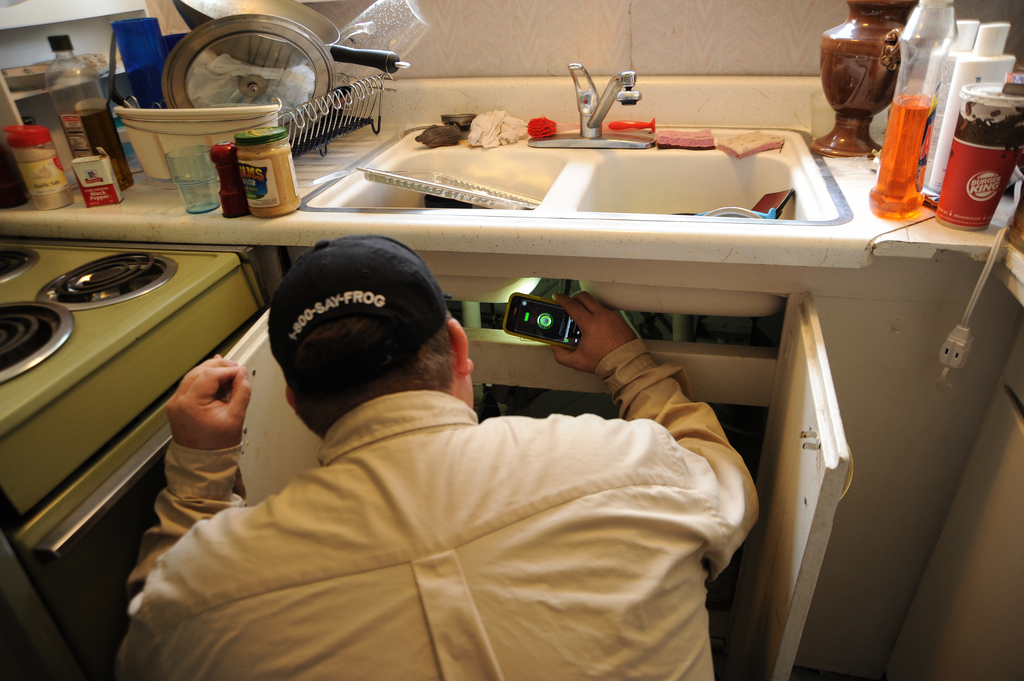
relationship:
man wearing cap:
[115, 237, 761, 678] [264, 234, 451, 404]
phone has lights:
[487, 277, 640, 389] [519, 297, 562, 333]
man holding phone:
[115, 237, 761, 678] [500, 292, 583, 352]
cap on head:
[265, 234, 452, 374] [265, 234, 481, 421]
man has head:
[115, 237, 761, 678] [265, 234, 481, 421]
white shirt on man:
[117, 342, 767, 678] [115, 237, 761, 678]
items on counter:
[879, 0, 1022, 226] [823, 134, 1024, 289]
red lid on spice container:
[9, 117, 51, 146] [7, 115, 68, 210]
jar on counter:
[232, 125, 296, 214] [0, 114, 393, 242]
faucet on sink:
[565, 60, 642, 134] [304, 118, 852, 224]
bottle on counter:
[41, 30, 141, 185] [0, 95, 403, 250]